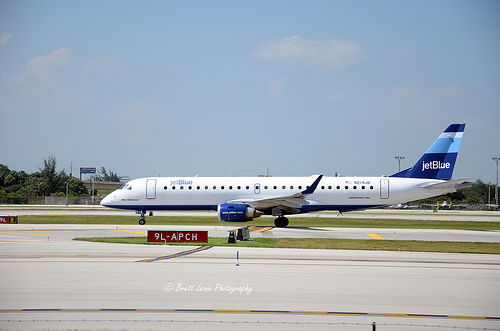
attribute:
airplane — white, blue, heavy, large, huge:
[100, 123, 460, 221]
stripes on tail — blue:
[410, 125, 465, 179]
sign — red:
[145, 230, 202, 243]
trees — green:
[1, 165, 86, 203]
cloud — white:
[262, 32, 356, 60]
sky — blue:
[1, 3, 498, 177]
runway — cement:
[6, 216, 496, 264]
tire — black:
[139, 217, 148, 225]